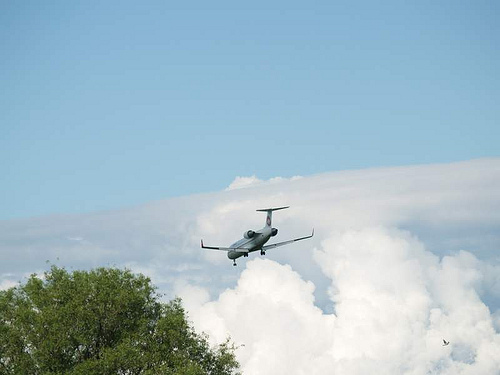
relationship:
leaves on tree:
[223, 333, 232, 343] [1, 260, 244, 373]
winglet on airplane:
[186, 207, 221, 264] [169, 166, 325, 271]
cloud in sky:
[0, 155, 499, 374] [1, 1, 497, 367]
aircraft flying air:
[201, 206, 315, 265] [33, 28, 298, 102]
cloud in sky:
[0, 155, 499, 374] [2, 3, 496, 227]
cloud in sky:
[310, 221, 440, 357] [2, 3, 496, 227]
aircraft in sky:
[201, 206, 315, 265] [1, 1, 497, 367]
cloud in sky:
[0, 155, 499, 374] [1, 2, 499, 322]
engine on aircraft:
[242, 230, 259, 240] [201, 206, 315, 265]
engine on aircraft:
[271, 226, 281, 235] [201, 206, 315, 265]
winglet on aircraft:
[200, 238, 251, 252] [201, 206, 315, 265]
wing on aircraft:
[264, 225, 315, 249] [201, 206, 315, 265]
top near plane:
[6, 262, 239, 367] [194, 200, 325, 281]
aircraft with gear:
[201, 206, 315, 265] [232, 256, 239, 272]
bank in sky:
[14, 167, 483, 300] [5, 8, 484, 273]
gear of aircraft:
[228, 256, 238, 266] [201, 206, 315, 265]